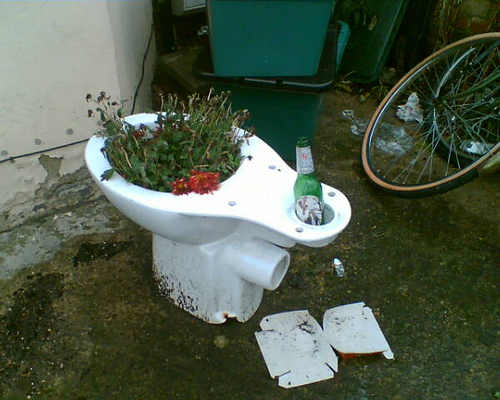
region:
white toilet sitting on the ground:
[85, 113, 350, 325]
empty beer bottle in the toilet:
[292, 138, 321, 225]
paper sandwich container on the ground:
[252, 303, 394, 389]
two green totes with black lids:
[195, 4, 347, 141]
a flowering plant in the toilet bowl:
[85, 92, 253, 192]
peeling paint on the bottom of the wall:
[2, 133, 125, 265]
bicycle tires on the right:
[362, 26, 499, 203]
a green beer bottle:
[292, 136, 322, 226]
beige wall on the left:
[0, 0, 159, 267]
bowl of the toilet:
[85, 110, 254, 243]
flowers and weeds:
[88, 92, 243, 195]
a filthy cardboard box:
[255, 311, 387, 379]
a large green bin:
[203, 0, 325, 84]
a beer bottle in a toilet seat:
[81, 103, 349, 314]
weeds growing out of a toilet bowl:
[89, 88, 247, 220]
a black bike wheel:
[369, 30, 499, 194]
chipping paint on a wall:
[0, 151, 84, 240]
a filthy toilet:
[93, 98, 361, 316]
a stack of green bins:
[211, 0, 333, 150]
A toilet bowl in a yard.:
[78, 83, 355, 335]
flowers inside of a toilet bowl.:
[63, 62, 253, 211]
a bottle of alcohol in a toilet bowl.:
[282, 132, 334, 235]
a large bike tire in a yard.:
[349, 21, 498, 208]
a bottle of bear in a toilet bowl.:
[285, 115, 330, 232]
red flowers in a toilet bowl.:
[160, 162, 234, 207]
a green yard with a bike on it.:
[0, 64, 499, 397]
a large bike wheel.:
[353, 20, 498, 197]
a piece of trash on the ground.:
[247, 292, 407, 397]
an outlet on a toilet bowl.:
[221, 237, 304, 307]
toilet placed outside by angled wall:
[6, 16, 366, 346]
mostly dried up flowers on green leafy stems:
[77, 76, 247, 206]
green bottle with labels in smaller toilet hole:
[290, 136, 335, 226]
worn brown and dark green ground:
[10, 10, 490, 390]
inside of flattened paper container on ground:
[255, 295, 395, 385]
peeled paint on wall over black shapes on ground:
[5, 145, 130, 342]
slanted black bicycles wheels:
[360, 25, 497, 205]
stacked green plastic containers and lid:
[200, 0, 401, 185]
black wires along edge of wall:
[0, 22, 185, 237]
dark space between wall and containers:
[130, 2, 216, 98]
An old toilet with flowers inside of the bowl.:
[80, 85, 350, 321]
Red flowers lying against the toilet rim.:
[162, 167, 218, 194]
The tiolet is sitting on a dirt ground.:
[7, 82, 497, 398]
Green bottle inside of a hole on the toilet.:
[290, 130, 326, 225]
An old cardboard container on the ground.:
[252, 300, 397, 388]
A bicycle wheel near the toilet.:
[357, 23, 497, 199]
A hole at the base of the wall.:
[65, 231, 142, 269]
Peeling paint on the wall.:
[0, 152, 130, 257]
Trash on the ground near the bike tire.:
[335, 85, 428, 160]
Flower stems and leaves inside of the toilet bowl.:
[83, 89, 258, 196]